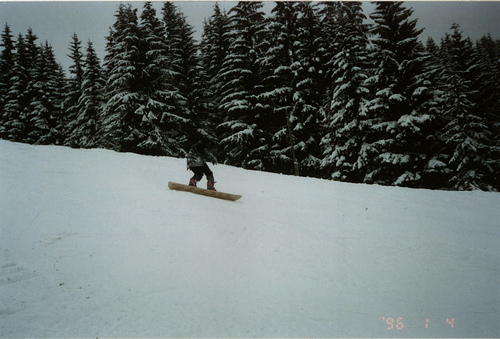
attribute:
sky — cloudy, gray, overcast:
[0, 1, 499, 81]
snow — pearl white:
[3, 142, 499, 337]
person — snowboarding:
[186, 139, 219, 190]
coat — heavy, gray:
[187, 143, 213, 169]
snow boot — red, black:
[205, 176, 215, 191]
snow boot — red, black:
[186, 176, 197, 190]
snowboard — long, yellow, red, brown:
[170, 182, 241, 201]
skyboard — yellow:
[167, 176, 242, 203]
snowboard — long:
[167, 178, 242, 205]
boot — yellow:
[206, 180, 218, 191]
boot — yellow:
[186, 175, 198, 188]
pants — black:
[189, 162, 214, 181]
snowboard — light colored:
[164, 176, 242, 204]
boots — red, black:
[184, 177, 219, 191]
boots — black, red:
[188, 177, 217, 190]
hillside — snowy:
[38, 160, 469, 320]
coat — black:
[186, 144, 212, 167]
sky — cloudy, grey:
[13, 4, 468, 35]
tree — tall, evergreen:
[52, 30, 85, 144]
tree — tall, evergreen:
[101, 2, 188, 154]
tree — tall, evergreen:
[197, 1, 235, 86]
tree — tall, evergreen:
[264, 2, 334, 181]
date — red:
[382, 312, 456, 330]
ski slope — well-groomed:
[6, 118, 493, 330]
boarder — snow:
[173, 127, 223, 190]